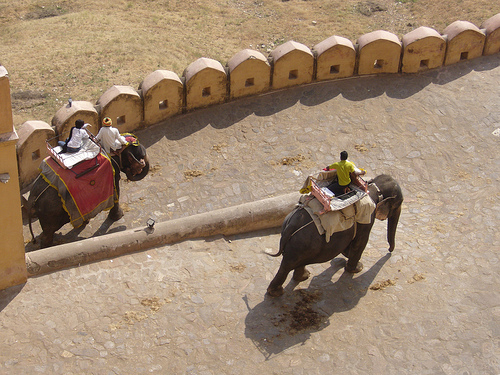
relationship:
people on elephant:
[73, 115, 117, 146] [38, 150, 171, 247]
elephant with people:
[38, 150, 171, 247] [93, 117, 130, 154]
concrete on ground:
[350, 81, 376, 155] [316, 101, 494, 161]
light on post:
[0, 164, 22, 197] [125, 208, 257, 257]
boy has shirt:
[61, 118, 90, 136] [70, 136, 107, 161]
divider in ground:
[131, 195, 257, 229] [316, 101, 494, 161]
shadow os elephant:
[36, 233, 100, 245] [38, 150, 171, 247]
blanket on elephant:
[77, 167, 132, 209] [38, 150, 171, 247]